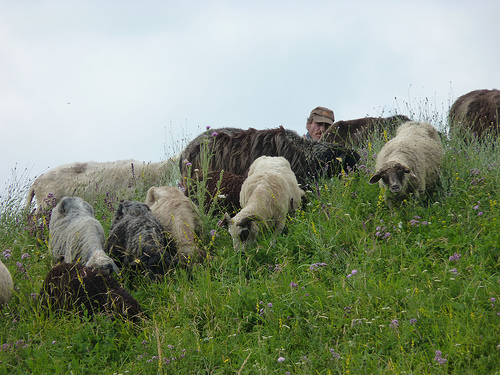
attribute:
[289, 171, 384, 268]
flowers — little, yellow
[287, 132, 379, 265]
grass — long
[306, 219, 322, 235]
flowers — yellow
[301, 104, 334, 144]
tom —  peeping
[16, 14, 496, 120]
sky — cloudy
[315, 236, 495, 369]
grass — beautiful, green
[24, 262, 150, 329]
animal — black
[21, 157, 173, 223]
animal — white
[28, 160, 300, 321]
animals —   man's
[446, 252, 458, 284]
weed —  lots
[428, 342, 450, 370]
weed —  lots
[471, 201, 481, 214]
weed —  lots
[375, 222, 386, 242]
weed —  lots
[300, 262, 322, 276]
weed —  lots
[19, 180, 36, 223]
tail —  animal's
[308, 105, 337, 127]
cap — brown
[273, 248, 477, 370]
flowers — purple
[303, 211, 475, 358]
grass — tall, green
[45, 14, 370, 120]
clouds — white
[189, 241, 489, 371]
grass — green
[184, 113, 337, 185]
hair — long